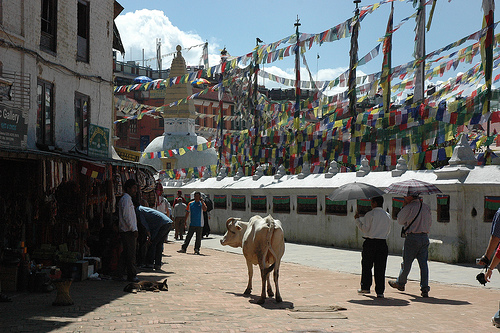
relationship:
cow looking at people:
[223, 217, 285, 295] [93, 176, 215, 274]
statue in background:
[155, 42, 208, 181] [199, 48, 223, 71]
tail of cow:
[258, 222, 279, 277] [240, 217, 285, 295]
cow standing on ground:
[240, 217, 285, 295] [105, 307, 224, 333]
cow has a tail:
[240, 217, 285, 295] [258, 222, 279, 277]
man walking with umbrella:
[330, 179, 392, 307] [326, 178, 387, 202]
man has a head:
[330, 179, 392, 307] [371, 194, 385, 207]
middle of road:
[197, 276, 219, 305] [306, 247, 341, 308]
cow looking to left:
[240, 217, 285, 295] [215, 231, 220, 253]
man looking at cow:
[330, 179, 392, 307] [240, 217, 285, 295]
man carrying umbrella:
[330, 179, 392, 307] [326, 178, 387, 202]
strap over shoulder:
[413, 208, 422, 224] [396, 206, 407, 222]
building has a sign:
[1, 5, 110, 139] [83, 118, 112, 162]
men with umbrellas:
[308, 167, 451, 330] [317, 170, 450, 205]